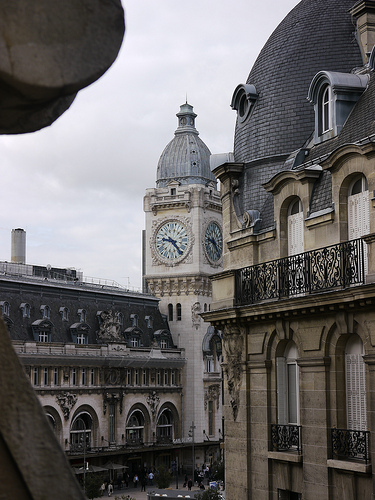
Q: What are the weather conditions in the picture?
A: It is cloudy.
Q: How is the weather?
A: It is cloudy.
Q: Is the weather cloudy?
A: Yes, it is cloudy.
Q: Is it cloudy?
A: Yes, it is cloudy.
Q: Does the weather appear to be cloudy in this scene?
A: Yes, it is cloudy.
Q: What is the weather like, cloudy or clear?
A: It is cloudy.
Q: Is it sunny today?
A: No, it is cloudy.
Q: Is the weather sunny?
A: No, it is cloudy.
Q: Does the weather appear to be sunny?
A: No, it is cloudy.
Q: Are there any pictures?
A: No, there are no pictures.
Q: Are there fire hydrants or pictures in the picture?
A: No, there are no pictures or fire hydrants.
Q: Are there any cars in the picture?
A: No, there are no cars.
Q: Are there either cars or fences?
A: No, there are no cars or fences.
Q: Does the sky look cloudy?
A: Yes, the sky is cloudy.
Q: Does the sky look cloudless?
A: No, the sky is cloudy.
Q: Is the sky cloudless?
A: No, the sky is cloudy.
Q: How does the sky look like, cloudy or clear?
A: The sky is cloudy.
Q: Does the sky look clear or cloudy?
A: The sky is cloudy.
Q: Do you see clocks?
A: Yes, there is a clock.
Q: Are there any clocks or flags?
A: Yes, there is a clock.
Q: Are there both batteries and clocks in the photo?
A: No, there is a clock but no batteries.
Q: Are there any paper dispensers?
A: No, there are no paper dispensers.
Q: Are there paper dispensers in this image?
A: No, there are no paper dispensers.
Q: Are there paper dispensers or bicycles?
A: No, there are no paper dispensers or bicycles.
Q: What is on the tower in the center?
A: The clock is on the tower.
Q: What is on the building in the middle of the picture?
A: The clock is on the tower.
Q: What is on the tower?
A: The clock is on the tower.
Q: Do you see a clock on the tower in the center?
A: Yes, there is a clock on the tower.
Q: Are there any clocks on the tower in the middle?
A: Yes, there is a clock on the tower.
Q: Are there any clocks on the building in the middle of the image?
A: Yes, there is a clock on the tower.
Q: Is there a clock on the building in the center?
A: Yes, there is a clock on the tower.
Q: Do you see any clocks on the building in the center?
A: Yes, there is a clock on the tower.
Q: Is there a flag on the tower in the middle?
A: No, there is a clock on the tower.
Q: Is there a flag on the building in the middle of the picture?
A: No, there is a clock on the tower.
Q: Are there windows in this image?
A: Yes, there is a window.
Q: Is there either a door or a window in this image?
A: Yes, there is a window.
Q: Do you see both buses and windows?
A: No, there is a window but no buses.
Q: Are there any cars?
A: No, there are no cars.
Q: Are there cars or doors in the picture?
A: No, there are no cars or doors.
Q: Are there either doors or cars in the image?
A: No, there are no cars or doors.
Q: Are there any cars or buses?
A: No, there are no cars or buses.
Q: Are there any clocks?
A: Yes, there is a clock.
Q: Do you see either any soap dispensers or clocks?
A: Yes, there is a clock.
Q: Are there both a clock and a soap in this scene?
A: No, there is a clock but no soaps.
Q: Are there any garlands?
A: No, there are no garlands.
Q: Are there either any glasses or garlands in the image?
A: No, there are no garlands or glasses.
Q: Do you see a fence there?
A: No, there are no fences.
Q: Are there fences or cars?
A: No, there are no fences or cars.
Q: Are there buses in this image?
A: No, there are no buses.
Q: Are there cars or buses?
A: No, there are no buses or cars.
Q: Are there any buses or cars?
A: No, there are no buses or cars.